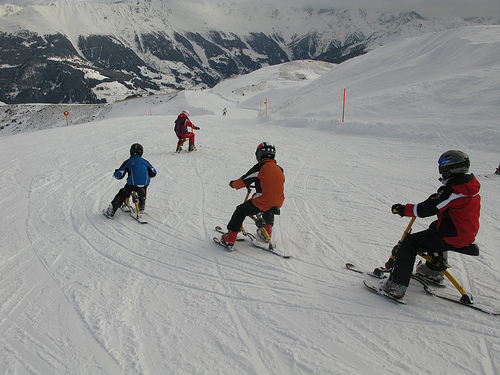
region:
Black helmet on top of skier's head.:
[256, 151, 263, 161]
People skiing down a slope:
[95, 86, 497, 288]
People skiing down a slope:
[90, 101, 208, 232]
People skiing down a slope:
[181, 132, 493, 344]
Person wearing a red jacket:
[402, 173, 482, 259]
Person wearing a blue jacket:
[105, 153, 160, 190]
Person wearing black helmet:
[123, 137, 154, 167]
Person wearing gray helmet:
[433, 145, 473, 176]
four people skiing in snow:
[91, 83, 495, 335]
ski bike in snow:
[336, 200, 495, 323]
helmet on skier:
[421, 141, 481, 188]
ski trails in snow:
[68, 168, 497, 358]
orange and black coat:
[217, 154, 294, 214]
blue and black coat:
[105, 153, 161, 191]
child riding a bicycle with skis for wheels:
[99, 137, 168, 234]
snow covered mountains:
[3, 1, 437, 111]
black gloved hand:
[384, 199, 408, 219]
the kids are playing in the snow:
[74, 83, 476, 340]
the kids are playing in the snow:
[77, 67, 490, 326]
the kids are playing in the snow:
[81, 93, 473, 330]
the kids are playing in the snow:
[76, 66, 465, 348]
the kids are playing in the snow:
[68, 59, 475, 316]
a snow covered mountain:
[19, 11, 314, 79]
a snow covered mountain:
[40, 8, 298, 104]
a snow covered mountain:
[44, 16, 296, 128]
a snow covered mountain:
[16, 7, 337, 131]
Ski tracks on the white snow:
[1, 105, 493, 370]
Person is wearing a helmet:
[427, 135, 472, 185]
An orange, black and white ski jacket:
[222, 150, 293, 225]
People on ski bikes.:
[103, 131, 475, 289]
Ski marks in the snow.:
[97, 232, 338, 328]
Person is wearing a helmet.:
[432, 156, 485, 190]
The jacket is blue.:
[121, 158, 151, 182]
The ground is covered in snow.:
[233, 86, 454, 187]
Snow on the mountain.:
[27, 8, 277, 72]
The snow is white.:
[33, 233, 379, 370]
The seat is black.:
[441, 238, 496, 256]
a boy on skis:
[222, 138, 285, 245]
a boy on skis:
[351, 148, 486, 313]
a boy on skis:
[102, 141, 166, 221]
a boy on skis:
[171, 110, 201, 150]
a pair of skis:
[206, 222, 295, 269]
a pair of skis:
[345, 257, 497, 322]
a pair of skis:
[90, 188, 150, 228]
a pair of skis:
[164, 142, 200, 157]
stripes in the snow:
[105, 208, 320, 313]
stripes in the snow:
[193, 140, 378, 259]